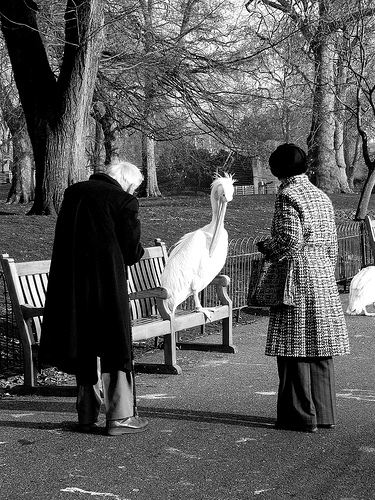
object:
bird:
[159, 169, 239, 321]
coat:
[264, 175, 351, 357]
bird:
[345, 263, 374, 317]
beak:
[208, 196, 227, 258]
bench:
[0, 236, 239, 398]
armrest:
[209, 273, 233, 287]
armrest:
[127, 286, 171, 300]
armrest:
[22, 303, 46, 321]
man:
[37, 154, 149, 435]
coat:
[38, 172, 146, 374]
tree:
[244, 0, 375, 221]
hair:
[106, 160, 145, 195]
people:
[254, 142, 350, 433]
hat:
[267, 142, 308, 180]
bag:
[246, 239, 297, 314]